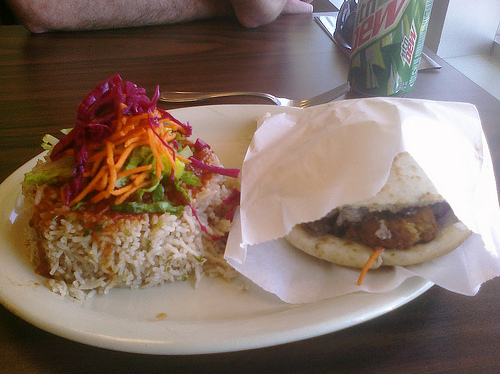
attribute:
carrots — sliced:
[80, 128, 134, 210]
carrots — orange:
[64, 110, 182, 208]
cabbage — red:
[46, 71, 192, 151]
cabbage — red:
[48, 70, 243, 215]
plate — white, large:
[0, 101, 435, 355]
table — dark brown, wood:
[0, 7, 495, 368]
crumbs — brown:
[158, 312, 168, 321]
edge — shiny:
[66, 326, 172, 351]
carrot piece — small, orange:
[353, 247, 384, 287]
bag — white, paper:
[222, 94, 483, 304]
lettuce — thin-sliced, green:
[22, 124, 202, 216]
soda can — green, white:
[347, 1, 433, 99]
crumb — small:
[148, 310, 167, 322]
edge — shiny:
[1, 279, 435, 357]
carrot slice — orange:
[354, 244, 382, 286]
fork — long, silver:
[156, 80, 349, 103]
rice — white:
[21, 145, 251, 303]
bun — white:
[284, 154, 473, 271]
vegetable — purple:
[49, 70, 239, 241]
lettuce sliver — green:
[112, 202, 185, 215]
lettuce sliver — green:
[132, 170, 162, 200]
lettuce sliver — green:
[41, 132, 60, 145]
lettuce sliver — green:
[40, 142, 52, 152]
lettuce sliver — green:
[20, 170, 59, 184]